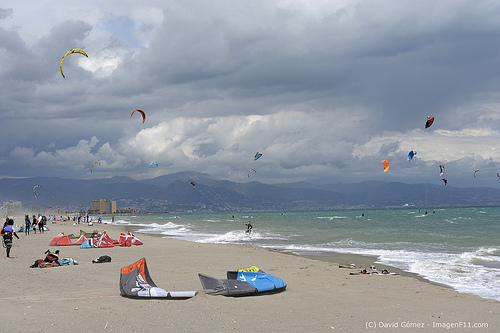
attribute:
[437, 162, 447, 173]
kite — white, blue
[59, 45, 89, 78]
sail — yellow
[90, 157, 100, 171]
sail — yellow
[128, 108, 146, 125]
sail — yellow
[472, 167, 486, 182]
sail — yellow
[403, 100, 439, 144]
kites — a Group, for surfing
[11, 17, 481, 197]
sky — cloudy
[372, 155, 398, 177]
kite — orange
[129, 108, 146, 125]
kite — red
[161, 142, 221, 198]
rope — white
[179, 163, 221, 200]
rope — white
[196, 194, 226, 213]
rope — white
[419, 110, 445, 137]
kite — multi colored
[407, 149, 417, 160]
kite — blue, white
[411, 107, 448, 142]
kite —  Yellow, for surfing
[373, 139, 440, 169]
kite — blue